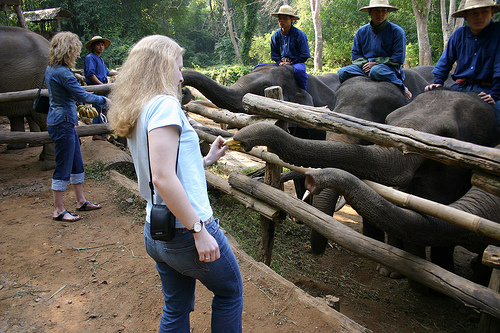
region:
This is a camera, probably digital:
[134, 187, 198, 247]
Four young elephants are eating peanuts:
[200, 46, 498, 286]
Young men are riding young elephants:
[233, 8, 498, 205]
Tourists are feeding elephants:
[199, 122, 259, 175]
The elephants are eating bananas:
[64, 90, 107, 131]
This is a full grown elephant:
[1, 18, 81, 165]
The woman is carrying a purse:
[26, 60, 79, 146]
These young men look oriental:
[247, 5, 496, 112]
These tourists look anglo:
[36, 16, 214, 196]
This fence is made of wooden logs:
[219, 83, 468, 299]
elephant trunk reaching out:
[304, 160, 469, 255]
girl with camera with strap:
[111, 34, 250, 328]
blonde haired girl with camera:
[121, 28, 236, 332]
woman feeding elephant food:
[128, 20, 226, 330]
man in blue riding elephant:
[405, 7, 496, 128]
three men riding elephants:
[228, 2, 498, 132]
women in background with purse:
[42, 25, 85, 230]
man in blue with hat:
[260, 5, 313, 67]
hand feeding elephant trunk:
[205, 121, 285, 157]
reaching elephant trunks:
[231, 110, 499, 257]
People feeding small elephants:
[7, 13, 499, 305]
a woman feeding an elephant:
[96, 26, 301, 330]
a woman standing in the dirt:
[28, 22, 117, 243]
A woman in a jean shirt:
[34, 8, 91, 127]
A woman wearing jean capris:
[35, 112, 97, 196]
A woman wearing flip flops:
[45, 198, 115, 226]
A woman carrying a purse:
[27, 58, 60, 123]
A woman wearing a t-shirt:
[99, 80, 231, 218]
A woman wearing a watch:
[174, 214, 212, 240]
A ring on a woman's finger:
[199, 250, 217, 265]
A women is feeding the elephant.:
[104, 33, 242, 332]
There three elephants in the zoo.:
[181, 61, 497, 291]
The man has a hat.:
[337, 0, 413, 98]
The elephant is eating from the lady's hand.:
[231, 90, 498, 198]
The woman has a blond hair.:
[46, 29, 111, 221]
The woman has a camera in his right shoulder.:
[108, 33, 241, 328]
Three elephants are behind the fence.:
[182, 66, 495, 258]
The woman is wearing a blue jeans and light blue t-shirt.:
[111, 34, 241, 331]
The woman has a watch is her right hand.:
[110, 36, 241, 332]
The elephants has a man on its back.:
[183, 0, 498, 244]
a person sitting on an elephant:
[251, 0, 333, 101]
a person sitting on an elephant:
[325, 0, 415, 116]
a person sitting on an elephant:
[421, 0, 495, 111]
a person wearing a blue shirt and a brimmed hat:
[268, 0, 315, 62]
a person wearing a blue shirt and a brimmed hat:
[346, 0, 408, 69]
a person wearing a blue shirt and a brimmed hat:
[423, 0, 498, 103]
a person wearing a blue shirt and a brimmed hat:
[84, 32, 116, 84]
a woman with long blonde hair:
[102, 25, 194, 136]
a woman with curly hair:
[44, 22, 87, 72]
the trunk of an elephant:
[236, 113, 416, 172]